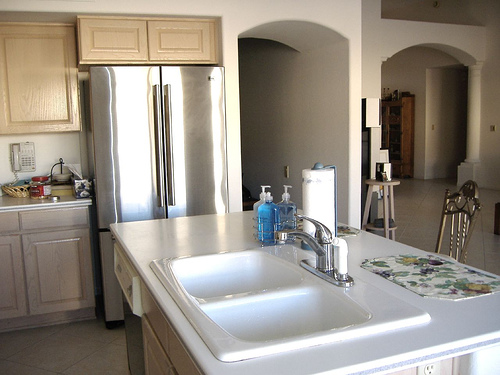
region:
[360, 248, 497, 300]
flower designed place mat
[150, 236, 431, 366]
white porcelain sink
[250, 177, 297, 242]
three bottles of soap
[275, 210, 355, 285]
a silver water faucet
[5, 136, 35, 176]
a white house phone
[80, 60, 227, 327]
a stainless steel fridge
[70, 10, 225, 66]
two tan small cabinets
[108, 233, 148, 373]
a white and silver dishwasher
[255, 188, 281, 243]
bottle of blue soap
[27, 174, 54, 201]
plastic jar of nuts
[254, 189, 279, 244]
bottle of blue fluid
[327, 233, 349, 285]
white sink sprayer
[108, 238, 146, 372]
white dishwasher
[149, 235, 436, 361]
clean white double kitchen sink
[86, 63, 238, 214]
Stainless steel refrigerator and freezer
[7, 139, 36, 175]
white phone mounted to the wall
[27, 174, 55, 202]
jar with red lid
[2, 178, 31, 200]
basket on the counter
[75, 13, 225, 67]
cabinet above the refrigerator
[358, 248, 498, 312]
place mat with a floral pattern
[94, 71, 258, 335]
a silver refridgerator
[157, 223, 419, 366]
a double white sink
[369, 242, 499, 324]
a placemate with green on it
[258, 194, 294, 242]
a bottle of blue soap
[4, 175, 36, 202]
bananas on the counter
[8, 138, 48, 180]
a white phone on the wall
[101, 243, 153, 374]
a dishwasher under the sink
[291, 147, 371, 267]
a roll of white paper towels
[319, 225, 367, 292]
a white spray nozzle on sink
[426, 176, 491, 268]
top of a brown chair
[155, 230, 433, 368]
double basin white sink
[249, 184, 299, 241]
pump bottles of soap on counter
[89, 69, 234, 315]
silver refrigerator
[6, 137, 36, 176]
white phone on wall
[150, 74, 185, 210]
handles of silver fridge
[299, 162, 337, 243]
roll of paper towels on counter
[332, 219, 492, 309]
place mats on white counter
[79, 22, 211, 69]
cabinets over the top of fridge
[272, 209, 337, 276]
silver faucet and handle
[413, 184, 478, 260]
chair sitting at kitchen island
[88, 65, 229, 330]
Large stainless steel refrigerator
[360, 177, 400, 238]
Barstool sitting in adjacent room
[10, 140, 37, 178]
Telephone hanging on kitchen wall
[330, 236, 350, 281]
Hand sprayer for kitchen sink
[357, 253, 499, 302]
Placemat sitting on the kitchen counter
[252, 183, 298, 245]
Several bottles of hand soap on the kitchen counter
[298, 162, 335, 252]
Paper towel dispenser sitting on the kitchen counter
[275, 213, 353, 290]
Faucet for kitchen sink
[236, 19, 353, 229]
Arched doorway into hallway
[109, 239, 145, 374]
Under the counter dishwasher